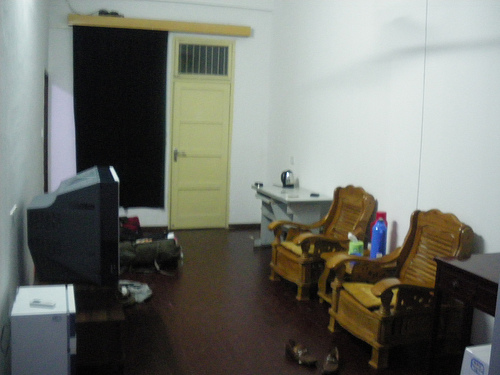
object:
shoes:
[285, 336, 317, 366]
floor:
[87, 323, 280, 374]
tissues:
[348, 231, 364, 255]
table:
[320, 250, 412, 269]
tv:
[23, 164, 123, 290]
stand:
[69, 302, 130, 366]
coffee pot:
[281, 170, 295, 188]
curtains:
[74, 28, 166, 205]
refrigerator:
[7, 280, 75, 375]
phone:
[310, 193, 320, 197]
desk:
[250, 183, 332, 243]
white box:
[460, 343, 490, 375]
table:
[434, 251, 500, 346]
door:
[170, 78, 233, 228]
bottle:
[369, 217, 387, 262]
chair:
[268, 184, 377, 303]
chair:
[326, 208, 479, 368]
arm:
[368, 271, 427, 297]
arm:
[292, 232, 340, 245]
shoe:
[321, 346, 340, 372]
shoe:
[285, 339, 319, 366]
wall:
[281, 8, 497, 183]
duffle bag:
[121, 236, 181, 277]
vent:
[177, 41, 228, 76]